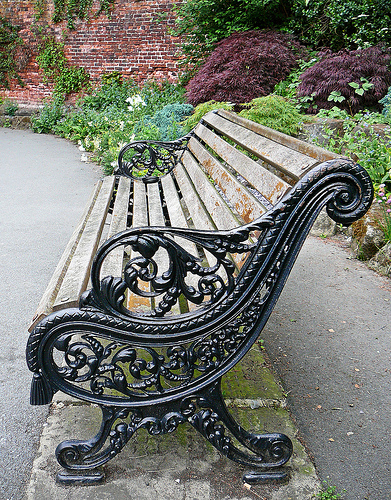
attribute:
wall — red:
[1, 2, 206, 110]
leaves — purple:
[184, 30, 390, 116]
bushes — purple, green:
[33, 0, 390, 253]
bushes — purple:
[180, 29, 390, 115]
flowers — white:
[78, 93, 148, 174]